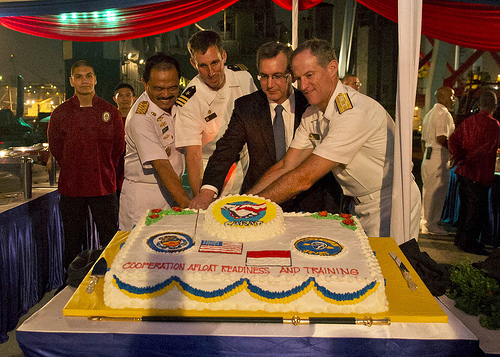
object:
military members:
[44, 29, 426, 260]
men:
[188, 38, 356, 217]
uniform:
[171, 65, 260, 197]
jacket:
[47, 92, 126, 199]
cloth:
[13, 283, 483, 356]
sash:
[0, 0, 242, 45]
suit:
[282, 180, 356, 215]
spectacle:
[0, 0, 500, 357]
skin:
[296, 59, 312, 66]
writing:
[121, 261, 360, 275]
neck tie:
[272, 104, 286, 162]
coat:
[199, 85, 353, 214]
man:
[243, 38, 423, 248]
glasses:
[257, 72, 287, 80]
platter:
[61, 229, 451, 324]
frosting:
[299, 220, 316, 231]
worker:
[46, 58, 127, 285]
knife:
[184, 207, 207, 214]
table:
[13, 239, 480, 356]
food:
[0, 141, 48, 159]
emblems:
[210, 195, 279, 228]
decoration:
[245, 249, 293, 269]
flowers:
[149, 214, 160, 220]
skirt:
[0, 187, 102, 341]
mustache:
[156, 95, 175, 101]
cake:
[102, 193, 390, 315]